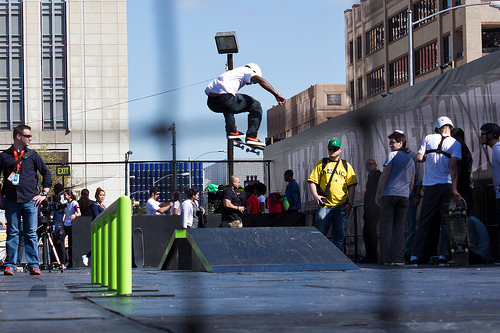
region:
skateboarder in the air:
[205, 63, 287, 153]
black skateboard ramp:
[156, 225, 356, 268]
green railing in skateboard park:
[90, 196, 131, 294]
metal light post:
[215, 31, 237, 181]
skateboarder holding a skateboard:
[412, 115, 472, 270]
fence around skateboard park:
[0, 157, 273, 254]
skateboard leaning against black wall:
[130, 226, 141, 268]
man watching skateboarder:
[0, 123, 53, 273]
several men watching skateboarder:
[305, 131, 410, 262]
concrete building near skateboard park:
[0, 3, 128, 257]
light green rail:
[87, 195, 139, 297]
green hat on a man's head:
[325, 137, 343, 149]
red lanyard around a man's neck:
[6, 149, 28, 187]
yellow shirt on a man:
[306, 159, 356, 206]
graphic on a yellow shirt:
[321, 166, 347, 183]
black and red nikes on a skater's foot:
[223, 128, 268, 145]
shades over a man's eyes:
[20, 131, 32, 138]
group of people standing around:
[0, 114, 498, 274]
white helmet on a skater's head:
[243, 60, 261, 75]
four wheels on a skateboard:
[228, 139, 263, 156]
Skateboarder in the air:
[194, 55, 295, 162]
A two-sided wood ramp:
[154, 221, 362, 281]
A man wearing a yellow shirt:
[302, 138, 360, 270]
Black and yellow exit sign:
[49, 155, 79, 190]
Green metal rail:
[81, 194, 154, 298]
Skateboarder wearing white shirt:
[203, 57, 288, 158]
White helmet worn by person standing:
[429, 112, 451, 137]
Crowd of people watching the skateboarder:
[4, 108, 498, 277]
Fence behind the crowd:
[29, 153, 284, 227]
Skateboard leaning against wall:
[125, 222, 150, 274]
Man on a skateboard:
[200, 64, 283, 160]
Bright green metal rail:
[87, 194, 137, 295]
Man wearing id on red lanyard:
[7, 123, 34, 189]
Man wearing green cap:
[310, 133, 358, 208]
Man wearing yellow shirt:
[302, 135, 357, 208]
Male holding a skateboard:
[416, 113, 470, 265]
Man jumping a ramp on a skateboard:
[198, 56, 290, 272]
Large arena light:
[210, 27, 241, 65]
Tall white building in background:
[73, 2, 125, 190]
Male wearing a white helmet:
[429, 112, 454, 141]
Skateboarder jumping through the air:
[133, 43, 363, 276]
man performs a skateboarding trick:
[145, 49, 371, 280]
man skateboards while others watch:
[5, 30, 485, 304]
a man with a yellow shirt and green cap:
[303, 132, 360, 269]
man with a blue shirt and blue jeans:
[2, 118, 57, 286]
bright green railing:
[76, 182, 165, 304]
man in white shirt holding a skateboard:
[408, 108, 476, 273]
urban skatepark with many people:
[0, 50, 499, 301]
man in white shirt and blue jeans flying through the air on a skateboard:
[195, 56, 292, 168]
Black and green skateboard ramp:
[145, 213, 367, 291]